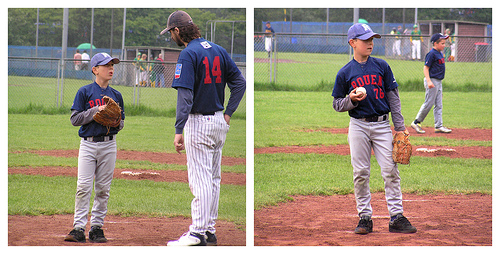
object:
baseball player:
[331, 21, 416, 233]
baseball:
[352, 85, 367, 97]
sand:
[253, 186, 493, 246]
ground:
[254, 43, 491, 243]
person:
[67, 52, 126, 242]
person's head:
[427, 31, 449, 53]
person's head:
[342, 17, 382, 57]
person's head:
[88, 51, 118, 85]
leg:
[411, 86, 439, 134]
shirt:
[168, 41, 237, 116]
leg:
[183, 123, 217, 232]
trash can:
[469, 41, 489, 63]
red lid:
[471, 40, 488, 49]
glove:
[94, 95, 123, 127]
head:
[87, 51, 122, 82]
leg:
[70, 136, 96, 230]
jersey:
[334, 58, 396, 119]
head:
[157, 7, 203, 43]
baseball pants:
[73, 136, 117, 231]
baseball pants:
[182, 115, 228, 236]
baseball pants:
[412, 76, 444, 128]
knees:
[74, 186, 92, 199]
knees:
[353, 168, 372, 187]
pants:
[349, 113, 405, 220]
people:
[73, 50, 82, 72]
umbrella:
[73, 41, 96, 51]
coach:
[157, 10, 248, 245]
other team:
[132, 51, 165, 86]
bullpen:
[383, 19, 485, 63]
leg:
[346, 124, 376, 219]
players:
[406, 26, 425, 61]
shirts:
[326, 55, 404, 118]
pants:
[263, 36, 273, 54]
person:
[410, 32, 457, 137]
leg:
[432, 78, 447, 134]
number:
[199, 50, 225, 87]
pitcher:
[326, 20, 417, 236]